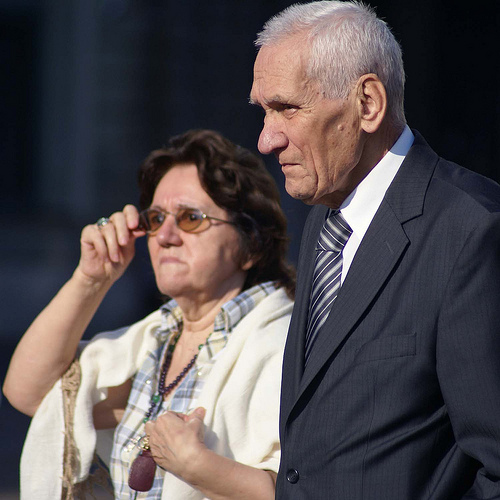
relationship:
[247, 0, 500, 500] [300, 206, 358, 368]
man wears tie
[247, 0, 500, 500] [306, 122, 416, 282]
man wears shirt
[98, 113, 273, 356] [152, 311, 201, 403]
woman wears necklace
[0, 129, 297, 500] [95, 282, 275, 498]
woman wears shirt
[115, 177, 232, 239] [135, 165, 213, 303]
glasses on face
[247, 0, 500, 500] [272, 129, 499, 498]
man wears coat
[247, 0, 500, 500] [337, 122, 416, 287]
man wears shirt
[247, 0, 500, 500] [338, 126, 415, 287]
man wears dress shirt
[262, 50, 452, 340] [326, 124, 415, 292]
man wears dress shirt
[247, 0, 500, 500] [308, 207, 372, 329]
man wears tie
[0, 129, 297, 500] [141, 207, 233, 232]
woman wearing glasses glasses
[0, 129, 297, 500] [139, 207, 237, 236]
woman wearing sun glasses glasses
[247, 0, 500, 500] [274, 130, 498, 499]
man wearing coat coat